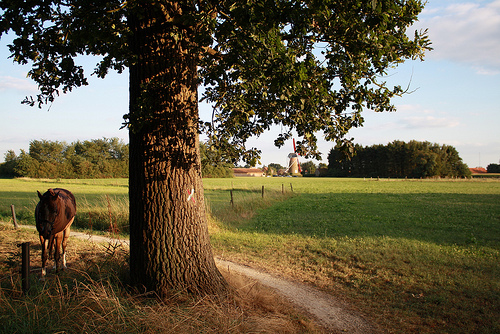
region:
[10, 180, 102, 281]
horse in the shade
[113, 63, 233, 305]
trunk of a tree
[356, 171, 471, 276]
green grass in a field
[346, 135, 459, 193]
green trees behind the grass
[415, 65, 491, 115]
blue sky in the distance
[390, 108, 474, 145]
clouds in the sky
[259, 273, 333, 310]
dirt path by a tree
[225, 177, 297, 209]
fence in the grass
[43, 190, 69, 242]
head of a horse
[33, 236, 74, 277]
legs of a horse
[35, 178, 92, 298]
A horse by the tree.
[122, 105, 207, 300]
The tree has a long trunk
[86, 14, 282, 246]
The green tree is big.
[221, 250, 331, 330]
A path in the grass.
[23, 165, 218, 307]
Animal under the tree.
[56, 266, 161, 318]
Branches on the ground.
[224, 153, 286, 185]
A building in the background.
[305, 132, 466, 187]
Trees next to the building.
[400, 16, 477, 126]
The sky has white clouds.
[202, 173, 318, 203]
A gate in the field.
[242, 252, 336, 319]
Small trail of sand.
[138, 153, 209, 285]
Brown tree stump with spots.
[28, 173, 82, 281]
Animal next to the tree.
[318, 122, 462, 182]
Big bush in the back.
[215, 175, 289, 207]
Small sticks in the ground.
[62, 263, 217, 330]
Small tan hay in the ground.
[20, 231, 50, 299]
Dark brown spot in the ground.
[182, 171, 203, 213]
Small white line on tree.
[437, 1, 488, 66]
Thin group of clouds.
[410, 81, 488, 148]
Clear thin blue sky.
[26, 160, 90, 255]
Horse near a tree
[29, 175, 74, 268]
Brown horse near a tree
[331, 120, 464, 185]
Group of trees in the field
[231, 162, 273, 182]
House in the field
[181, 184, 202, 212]
painted X on a tree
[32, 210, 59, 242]
Strap on a horse mouth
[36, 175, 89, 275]
Horse near a large tree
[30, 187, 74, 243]
Horse with perked up ears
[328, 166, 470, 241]
Lush field of grass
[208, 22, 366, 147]
leaves on a tree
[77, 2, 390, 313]
Healthy tree with green leaves.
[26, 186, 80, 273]
Donkey standing by tree.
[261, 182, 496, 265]
Big shadow on grass.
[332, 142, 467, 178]
Group of trees in background.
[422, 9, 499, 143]
White and gray clouds in sky.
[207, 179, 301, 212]
Small wooden fence in field.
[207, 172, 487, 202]
Sun shining on green grass.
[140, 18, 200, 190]
Shadow of leaves on tree trunk.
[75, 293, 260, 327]
Dry grass by tree.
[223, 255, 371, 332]
Small gravel path.